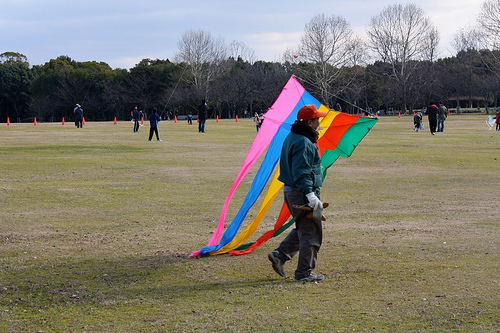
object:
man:
[266, 104, 329, 281]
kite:
[189, 74, 379, 258]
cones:
[32, 116, 40, 125]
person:
[494, 111, 500, 130]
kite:
[486, 113, 497, 132]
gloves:
[305, 191, 325, 210]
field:
[0, 117, 499, 332]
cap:
[296, 104, 329, 122]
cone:
[32, 117, 38, 127]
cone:
[112, 117, 118, 126]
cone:
[215, 114, 220, 122]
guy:
[196, 96, 210, 134]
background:
[0, 1, 498, 155]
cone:
[3, 116, 13, 126]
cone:
[397, 111, 404, 119]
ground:
[4, 232, 499, 331]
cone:
[234, 114, 240, 122]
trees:
[32, 54, 108, 125]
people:
[74, 105, 84, 129]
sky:
[1, 0, 499, 71]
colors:
[260, 123, 356, 149]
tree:
[175, 29, 252, 120]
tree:
[366, 1, 441, 114]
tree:
[286, 14, 366, 115]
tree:
[445, 1, 499, 104]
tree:
[0, 52, 34, 122]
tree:
[47, 56, 100, 123]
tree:
[252, 62, 293, 115]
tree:
[367, 62, 405, 109]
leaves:
[142, 59, 149, 66]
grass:
[46, 259, 72, 277]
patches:
[48, 234, 181, 323]